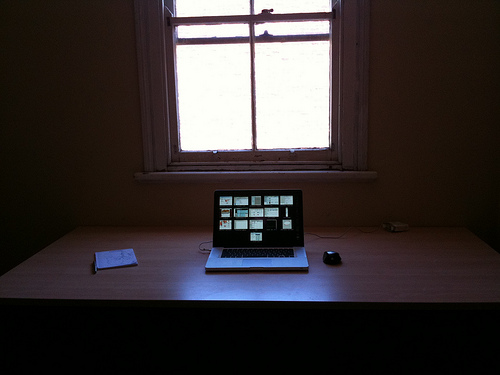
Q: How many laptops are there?
A: One.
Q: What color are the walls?
A: White.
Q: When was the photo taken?
A: Day time.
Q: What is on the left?
A: A book.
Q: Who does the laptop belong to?
A: A man.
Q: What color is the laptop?
A: Silver.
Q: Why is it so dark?
A: Dim light.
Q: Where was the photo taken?
A: In an office at home.